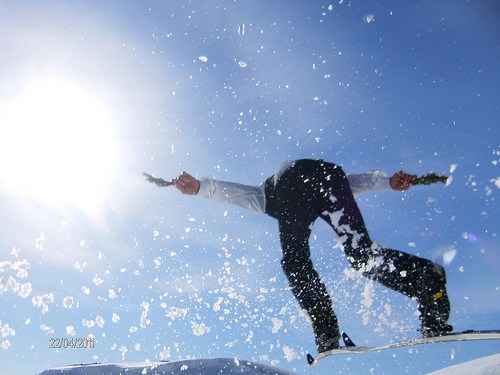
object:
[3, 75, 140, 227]
sun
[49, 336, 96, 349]
date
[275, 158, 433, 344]
pants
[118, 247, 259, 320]
snow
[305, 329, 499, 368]
board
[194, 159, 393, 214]
shirt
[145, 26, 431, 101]
sky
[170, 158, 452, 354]
man